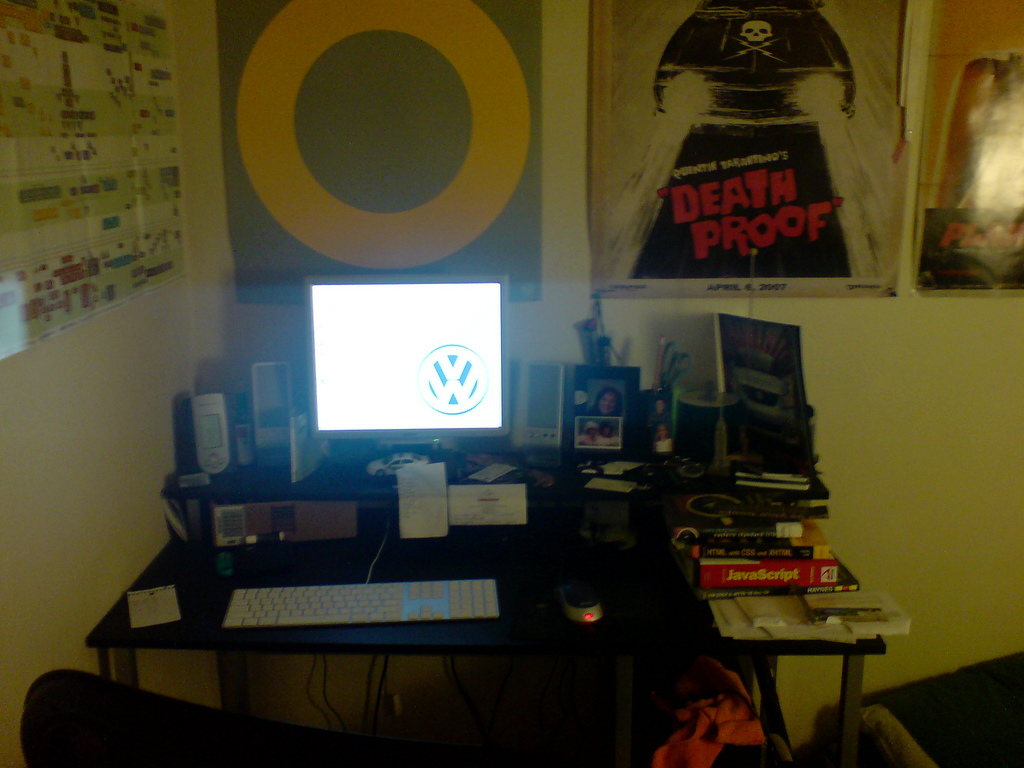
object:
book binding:
[700, 558, 840, 587]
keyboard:
[219, 579, 501, 632]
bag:
[644, 647, 766, 768]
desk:
[76, 458, 918, 763]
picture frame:
[566, 366, 641, 456]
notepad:
[124, 581, 179, 632]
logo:
[414, 344, 493, 416]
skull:
[739, 17, 774, 43]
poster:
[905, 0, 1024, 304]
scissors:
[655, 340, 697, 396]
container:
[672, 386, 747, 473]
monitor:
[302, 271, 509, 453]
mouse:
[554, 585, 606, 625]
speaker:
[186, 388, 234, 477]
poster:
[209, 1, 550, 303]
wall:
[0, 0, 199, 768]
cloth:
[647, 657, 765, 768]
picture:
[574, 416, 624, 452]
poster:
[583, 0, 906, 302]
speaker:
[249, 357, 312, 483]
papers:
[394, 461, 449, 543]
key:
[227, 612, 254, 619]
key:
[242, 618, 258, 628]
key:
[259, 616, 278, 626]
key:
[369, 613, 386, 624]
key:
[223, 618, 243, 628]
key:
[277, 616, 351, 626]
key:
[384, 614, 402, 622]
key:
[406, 613, 422, 623]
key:
[350, 614, 370, 625]